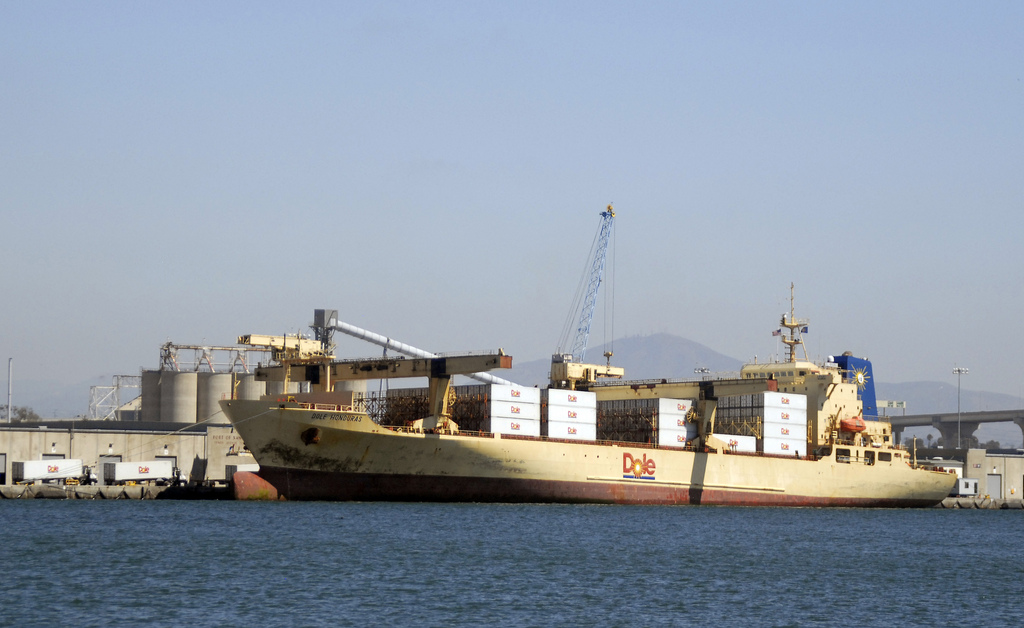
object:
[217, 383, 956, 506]
ship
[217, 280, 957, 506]
ship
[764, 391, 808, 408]
container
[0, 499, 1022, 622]
water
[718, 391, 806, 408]
container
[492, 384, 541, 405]
container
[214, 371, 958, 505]
container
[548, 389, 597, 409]
container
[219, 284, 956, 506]
container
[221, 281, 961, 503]
boat